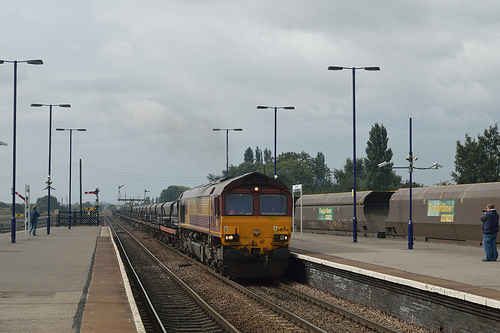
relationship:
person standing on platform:
[28, 204, 40, 237] [1, 224, 146, 332]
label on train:
[193, 197, 206, 219] [111, 170, 294, 281]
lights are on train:
[222, 233, 240, 241] [111, 170, 294, 281]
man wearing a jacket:
[481, 202, 499, 261] [480, 209, 500, 233]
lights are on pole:
[327, 63, 383, 73] [351, 67, 360, 243]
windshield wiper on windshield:
[279, 193, 286, 214] [224, 190, 291, 216]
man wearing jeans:
[481, 202, 499, 261] [483, 230, 500, 260]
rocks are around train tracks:
[118, 216, 304, 332] [102, 205, 500, 332]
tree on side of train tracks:
[450, 122, 499, 182] [102, 205, 500, 332]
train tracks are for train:
[102, 205, 500, 332] [111, 170, 294, 281]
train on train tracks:
[111, 170, 294, 281] [102, 205, 500, 332]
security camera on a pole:
[377, 158, 389, 170] [407, 116, 416, 250]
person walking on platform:
[28, 204, 40, 237] [1, 224, 146, 332]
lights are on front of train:
[222, 233, 240, 241] [111, 170, 294, 281]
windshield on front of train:
[224, 190, 291, 216] [111, 170, 294, 281]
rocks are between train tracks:
[118, 216, 304, 332] [102, 205, 500, 332]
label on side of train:
[193, 197, 206, 219] [111, 170, 294, 281]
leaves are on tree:
[450, 142, 494, 170] [450, 122, 499, 182]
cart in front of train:
[176, 171, 301, 301] [111, 170, 294, 281]